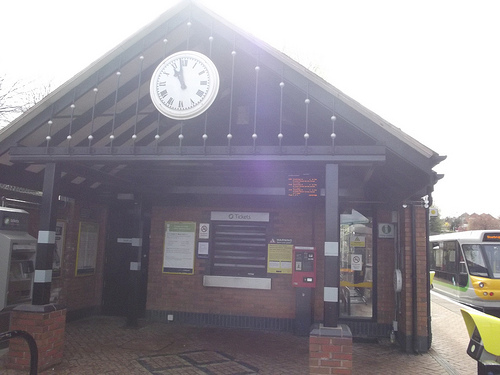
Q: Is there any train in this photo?
A: Yes, there is a train.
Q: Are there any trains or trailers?
A: Yes, there is a train.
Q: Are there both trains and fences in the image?
A: No, there is a train but no fences.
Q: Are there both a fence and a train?
A: No, there is a train but no fences.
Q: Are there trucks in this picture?
A: No, there are no trucks.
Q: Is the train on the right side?
A: Yes, the train is on the right of the image.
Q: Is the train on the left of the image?
A: No, the train is on the right of the image.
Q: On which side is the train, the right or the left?
A: The train is on the right of the image.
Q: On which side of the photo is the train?
A: The train is on the right of the image.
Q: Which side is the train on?
A: The train is on the right of the image.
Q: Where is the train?
A: The train is at the train station.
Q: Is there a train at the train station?
A: Yes, there is a train at the train station.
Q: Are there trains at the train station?
A: Yes, there is a train at the train station.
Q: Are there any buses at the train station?
A: No, there is a train at the train station.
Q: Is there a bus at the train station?
A: No, there is a train at the train station.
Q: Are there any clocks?
A: Yes, there is a clock.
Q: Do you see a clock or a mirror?
A: Yes, there is a clock.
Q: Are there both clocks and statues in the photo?
A: No, there is a clock but no statues.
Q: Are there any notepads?
A: No, there are no notepads.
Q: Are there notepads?
A: No, there are no notepads.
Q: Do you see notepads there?
A: No, there are no notepads.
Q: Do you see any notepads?
A: No, there are no notepads.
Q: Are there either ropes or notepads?
A: No, there are no notepads or ropes.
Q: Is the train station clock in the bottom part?
A: No, the clock is in the top of the image.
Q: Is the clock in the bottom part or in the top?
A: The clock is in the top of the image.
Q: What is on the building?
A: The clock is on the building.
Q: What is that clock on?
A: The clock is on the building.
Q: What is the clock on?
A: The clock is on the building.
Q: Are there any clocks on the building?
A: Yes, there is a clock on the building.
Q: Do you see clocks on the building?
A: Yes, there is a clock on the building.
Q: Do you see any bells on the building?
A: No, there is a clock on the building.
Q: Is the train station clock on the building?
A: Yes, the clock is on the building.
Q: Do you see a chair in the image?
A: No, there are no chairs.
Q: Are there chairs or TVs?
A: No, there are no chairs or tvs.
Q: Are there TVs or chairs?
A: No, there are no chairs or tvs.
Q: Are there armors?
A: No, there are no armors.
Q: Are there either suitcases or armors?
A: No, there are no armors or suitcases.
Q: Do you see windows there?
A: Yes, there is a window.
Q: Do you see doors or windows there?
A: Yes, there is a window.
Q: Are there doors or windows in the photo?
A: Yes, there is a window.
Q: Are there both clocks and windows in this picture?
A: Yes, there are both a window and a clock.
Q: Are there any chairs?
A: No, there are no chairs.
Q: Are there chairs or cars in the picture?
A: No, there are no chairs or cars.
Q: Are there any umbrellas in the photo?
A: No, there are no umbrellas.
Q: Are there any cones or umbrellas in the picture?
A: No, there are no umbrellas or cones.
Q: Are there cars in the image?
A: No, there are no cars.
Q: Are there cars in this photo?
A: No, there are no cars.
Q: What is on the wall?
A: The sign is on the wall.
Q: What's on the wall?
A: The sign is on the wall.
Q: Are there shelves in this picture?
A: No, there are no shelves.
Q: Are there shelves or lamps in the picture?
A: No, there are no shelves or lamps.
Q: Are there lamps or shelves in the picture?
A: No, there are no shelves or lamps.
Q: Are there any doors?
A: Yes, there is a door.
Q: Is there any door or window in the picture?
A: Yes, there is a door.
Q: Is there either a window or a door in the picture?
A: Yes, there is a door.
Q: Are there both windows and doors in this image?
A: Yes, there are both a door and windows.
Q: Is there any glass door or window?
A: Yes, there is a glass door.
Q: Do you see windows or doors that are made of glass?
A: Yes, the door is made of glass.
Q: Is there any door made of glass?
A: Yes, there is a door that is made of glass.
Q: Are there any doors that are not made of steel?
A: Yes, there is a door that is made of glass.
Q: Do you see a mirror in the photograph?
A: No, there are no mirrors.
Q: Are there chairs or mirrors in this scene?
A: No, there are no mirrors or chairs.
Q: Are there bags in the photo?
A: No, there are no bags.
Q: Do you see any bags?
A: No, there are no bags.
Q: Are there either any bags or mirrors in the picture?
A: No, there are no bags or mirrors.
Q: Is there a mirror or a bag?
A: No, there are no bags or mirrors.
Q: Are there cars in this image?
A: No, there are no cars.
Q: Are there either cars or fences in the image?
A: No, there are no cars or fences.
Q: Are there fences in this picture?
A: No, there are no fences.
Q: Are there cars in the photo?
A: No, there are no cars.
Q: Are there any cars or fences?
A: No, there are no cars or fences.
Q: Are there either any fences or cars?
A: No, there are no cars or fences.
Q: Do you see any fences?
A: No, there are no fences.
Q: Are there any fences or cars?
A: No, there are no fences or cars.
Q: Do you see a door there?
A: Yes, there is a door.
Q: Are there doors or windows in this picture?
A: Yes, there is a door.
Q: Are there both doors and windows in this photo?
A: Yes, there are both a door and a window.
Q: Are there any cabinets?
A: No, there are no cabinets.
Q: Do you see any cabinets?
A: No, there are no cabinets.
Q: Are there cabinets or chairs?
A: No, there are no cabinets or chairs.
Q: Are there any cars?
A: No, there are no cars.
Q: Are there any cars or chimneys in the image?
A: No, there are no cars or chimneys.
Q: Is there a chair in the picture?
A: No, there are no chairs.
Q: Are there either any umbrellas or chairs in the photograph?
A: No, there are no chairs or umbrellas.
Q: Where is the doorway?
A: The doorway is at the train station.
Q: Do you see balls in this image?
A: No, there are no balls.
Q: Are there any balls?
A: No, there are no balls.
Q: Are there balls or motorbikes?
A: No, there are no balls or motorbikes.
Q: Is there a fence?
A: No, there are no fences.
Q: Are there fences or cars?
A: No, there are no fences or cars.